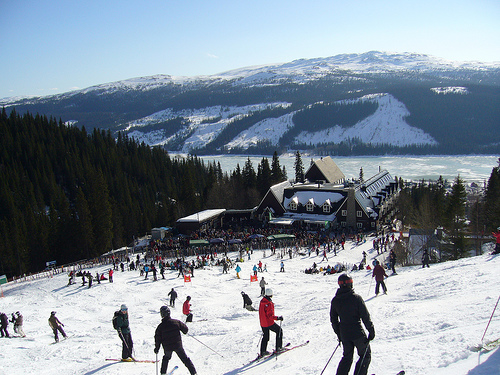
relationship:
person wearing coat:
[248, 285, 289, 365] [259, 296, 275, 326]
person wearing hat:
[256, 285, 284, 357] [264, 287, 273, 297]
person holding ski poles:
[372, 259, 387, 295] [253, 320, 290, 357]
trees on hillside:
[2, 0, 311, 150] [3, 111, 233, 302]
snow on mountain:
[231, 120, 308, 161] [198, 68, 436, 160]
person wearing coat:
[256, 285, 284, 357] [259, 296, 275, 326]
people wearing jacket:
[329, 272, 373, 374] [331, 285, 368, 339]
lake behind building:
[162, 147, 495, 192] [185, 157, 405, 236]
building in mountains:
[176, 207, 228, 239] [9, 51, 483, 370]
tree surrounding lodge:
[94, 197, 114, 257] [161, 151, 411, 238]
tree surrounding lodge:
[267, 146, 282, 186] [161, 151, 411, 238]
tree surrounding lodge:
[444, 171, 468, 221] [161, 151, 411, 238]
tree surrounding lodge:
[153, 190, 172, 224] [161, 151, 411, 238]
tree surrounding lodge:
[232, 156, 242, 192] [161, 151, 411, 238]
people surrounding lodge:
[17, 235, 394, 367] [147, 149, 399, 238]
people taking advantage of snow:
[329, 272, 373, 374] [2, 280, 498, 373]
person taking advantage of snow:
[256, 285, 284, 357] [2, 280, 498, 373]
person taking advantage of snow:
[152, 305, 196, 374] [2, 280, 498, 373]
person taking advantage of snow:
[372, 259, 387, 295] [2, 280, 498, 373]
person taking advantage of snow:
[112, 302, 134, 359] [2, 280, 498, 373]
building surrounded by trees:
[230, 153, 397, 241] [400, 170, 485, 250]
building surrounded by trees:
[230, 153, 397, 241] [0, 114, 304, 292]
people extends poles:
[329, 272, 373, 374] [311, 338, 371, 372]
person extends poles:
[256, 285, 284, 357] [253, 313, 285, 358]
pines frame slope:
[1, 103, 296, 285] [1, 222, 498, 373]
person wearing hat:
[256, 285, 284, 357] [257, 286, 273, 296]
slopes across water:
[106, 82, 491, 146] [374, 160, 482, 182]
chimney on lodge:
[341, 184, 361, 231] [159, 160, 404, 237]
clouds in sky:
[201, 45, 228, 65] [0, 0, 499, 102]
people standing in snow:
[329, 272, 373, 374] [0, 234, 497, 374]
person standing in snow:
[256, 285, 284, 357] [243, 355, 303, 374]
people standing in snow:
[329, 272, 373, 374] [296, 304, 323, 340]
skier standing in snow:
[44, 309, 74, 343] [25, 345, 92, 373]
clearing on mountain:
[433, 78, 470, 100] [1, 43, 497, 153]